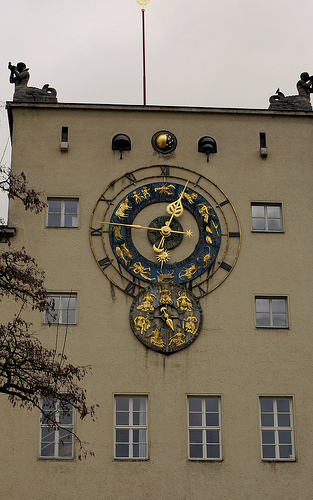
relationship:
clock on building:
[92, 158, 245, 321] [61, 73, 300, 380]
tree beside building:
[1, 132, 101, 461] [2, 99, 310, 498]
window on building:
[259, 394, 295, 462] [2, 99, 310, 498]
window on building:
[249, 202, 281, 232] [2, 99, 310, 498]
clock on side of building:
[85, 163, 243, 357] [2, 99, 310, 498]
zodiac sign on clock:
[108, 183, 220, 279] [97, 173, 233, 295]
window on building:
[44, 195, 80, 225] [2, 99, 310, 498]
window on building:
[41, 290, 76, 324] [2, 99, 310, 498]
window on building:
[252, 293, 287, 325] [2, 99, 310, 498]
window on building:
[39, 390, 75, 458] [2, 99, 310, 498]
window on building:
[112, 394, 150, 462] [2, 99, 310, 498]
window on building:
[187, 394, 223, 463] [2, 99, 310, 498]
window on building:
[107, 393, 148, 463] [2, 99, 310, 498]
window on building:
[27, 379, 81, 463] [51, 101, 296, 285]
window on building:
[103, 385, 163, 467] [51, 101, 296, 285]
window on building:
[175, 386, 236, 472] [51, 101, 296, 285]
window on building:
[247, 384, 302, 471] [51, 101, 296, 285]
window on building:
[36, 283, 84, 326] [51, 101, 296, 285]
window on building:
[255, 293, 289, 328] [51, 101, 296, 285]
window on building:
[41, 186, 85, 236] [51, 101, 296, 285]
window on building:
[249, 202, 281, 232] [51, 101, 296, 285]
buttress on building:
[251, 128, 276, 166] [2, 99, 310, 498]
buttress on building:
[55, 122, 73, 150] [2, 99, 310, 498]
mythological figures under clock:
[124, 286, 214, 355] [87, 163, 242, 300]